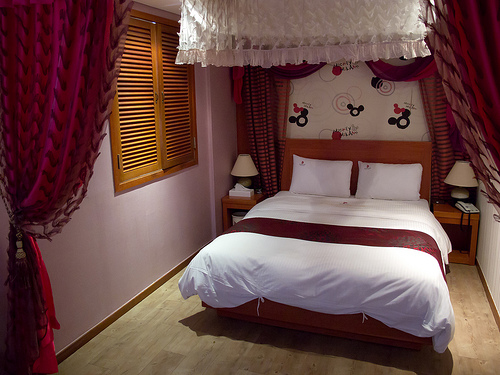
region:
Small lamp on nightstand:
[228, 152, 260, 187]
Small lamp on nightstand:
[442, 157, 479, 205]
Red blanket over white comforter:
[222, 212, 447, 279]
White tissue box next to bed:
[225, 183, 255, 197]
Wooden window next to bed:
[107, 10, 204, 197]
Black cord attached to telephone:
[456, 212, 471, 254]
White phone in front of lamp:
[454, 199, 481, 214]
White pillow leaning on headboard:
[354, 159, 426, 199]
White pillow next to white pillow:
[288, 154, 353, 196]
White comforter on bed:
[177, 191, 454, 354]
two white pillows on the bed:
[274, 142, 435, 214]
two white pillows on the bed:
[258, 146, 429, 221]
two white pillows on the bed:
[271, 135, 461, 210]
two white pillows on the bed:
[275, 139, 455, 210]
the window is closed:
[100, 10, 220, 194]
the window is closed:
[76, 10, 225, 235]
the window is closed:
[90, 0, 225, 202]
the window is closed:
[87, 3, 217, 202]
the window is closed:
[76, 2, 235, 214]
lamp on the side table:
[229, 155, 258, 189]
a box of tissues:
[227, 185, 257, 197]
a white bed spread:
[195, 187, 457, 344]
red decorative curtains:
[4, 3, 121, 361]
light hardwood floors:
[76, 265, 496, 370]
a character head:
[387, 102, 411, 129]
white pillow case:
[353, 161, 422, 199]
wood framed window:
[103, 12, 201, 197]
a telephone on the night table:
[453, 198, 479, 216]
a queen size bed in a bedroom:
[191, 135, 449, 352]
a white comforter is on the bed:
[203, 183, 450, 348]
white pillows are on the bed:
[288, 147, 425, 201]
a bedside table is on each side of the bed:
[218, 147, 478, 268]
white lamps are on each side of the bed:
[230, 150, 481, 208]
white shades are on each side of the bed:
[226, 153, 478, 189]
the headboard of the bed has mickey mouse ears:
[286, 53, 431, 141]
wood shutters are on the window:
[109, 8, 199, 192]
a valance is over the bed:
[168, 0, 444, 62]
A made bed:
[178, 135, 458, 373]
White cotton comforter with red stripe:
[176, 193, 458, 354]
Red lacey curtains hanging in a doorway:
[5, 6, 139, 373]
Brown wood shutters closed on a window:
[105, 1, 200, 197]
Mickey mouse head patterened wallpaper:
[289, 58, 420, 142]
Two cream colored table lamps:
[226, 153, 478, 205]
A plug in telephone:
[455, 199, 481, 231]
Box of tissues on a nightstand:
[225, 183, 252, 198]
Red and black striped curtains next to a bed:
[235, 70, 455, 209]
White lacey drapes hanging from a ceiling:
[172, 1, 432, 68]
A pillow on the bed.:
[292, 155, 362, 205]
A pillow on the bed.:
[343, 159, 425, 205]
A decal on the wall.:
[385, 110, 406, 130]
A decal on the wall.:
[289, 107, 311, 126]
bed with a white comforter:
[181, 126, 455, 361]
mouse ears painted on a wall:
[284, 62, 424, 143]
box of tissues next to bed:
[224, 179, 257, 198]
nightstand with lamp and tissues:
[221, 152, 264, 224]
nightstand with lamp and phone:
[426, 153, 482, 265]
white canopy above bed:
[175, 1, 444, 68]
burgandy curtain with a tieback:
[1, 7, 113, 374]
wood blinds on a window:
[106, 6, 199, 193]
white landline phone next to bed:
[451, 197, 482, 224]